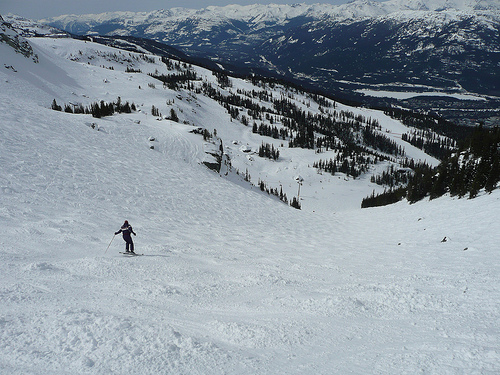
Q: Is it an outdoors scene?
A: Yes, it is outdoors.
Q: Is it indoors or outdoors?
A: It is outdoors.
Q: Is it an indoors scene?
A: No, it is outdoors.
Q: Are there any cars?
A: No, there are no cars.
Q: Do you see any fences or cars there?
A: No, there are no cars or fences.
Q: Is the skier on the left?
A: Yes, the skier is on the left of the image.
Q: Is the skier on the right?
A: No, the skier is on the left of the image.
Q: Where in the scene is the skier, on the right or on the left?
A: The skier is on the left of the image.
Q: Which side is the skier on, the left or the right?
A: The skier is on the left of the image.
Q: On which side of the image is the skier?
A: The skier is on the left of the image.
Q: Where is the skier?
A: The skier is in the snow.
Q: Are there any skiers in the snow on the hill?
A: Yes, there is a skier in the snow.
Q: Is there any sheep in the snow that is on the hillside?
A: No, there is a skier in the snow.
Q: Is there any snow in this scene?
A: Yes, there is snow.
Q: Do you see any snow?
A: Yes, there is snow.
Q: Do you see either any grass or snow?
A: Yes, there is snow.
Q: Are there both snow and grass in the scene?
A: No, there is snow but no grass.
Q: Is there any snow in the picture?
A: Yes, there is snow.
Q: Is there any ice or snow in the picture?
A: Yes, there is snow.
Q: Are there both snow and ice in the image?
A: No, there is snow but no ice.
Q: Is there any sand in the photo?
A: No, there is no sand.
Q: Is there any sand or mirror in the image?
A: No, there are no sand or mirrors.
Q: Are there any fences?
A: No, there are no fences.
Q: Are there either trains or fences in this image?
A: No, there are no fences or trains.